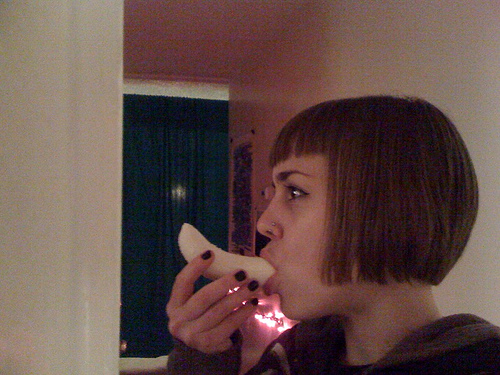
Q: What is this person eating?
A: A banana.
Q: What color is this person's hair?
A: Brown.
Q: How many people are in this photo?
A: One.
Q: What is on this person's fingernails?
A: Nail polish.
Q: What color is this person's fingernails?
A: Black.